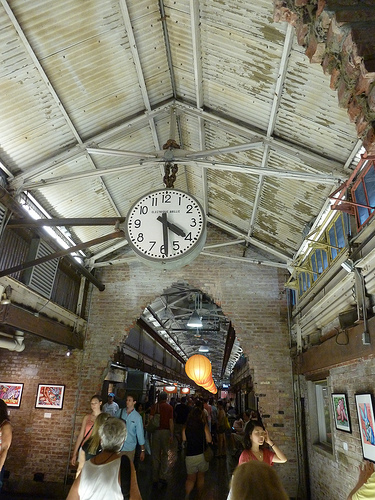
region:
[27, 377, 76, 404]
large picture on wall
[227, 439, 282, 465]
woman wearing red shirt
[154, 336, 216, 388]
large round orange light in ceiling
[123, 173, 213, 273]
large white and gray clock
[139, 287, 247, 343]
silver overhead beams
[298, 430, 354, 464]
gray ledge on window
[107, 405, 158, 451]
man wearing long sleeve blue shirt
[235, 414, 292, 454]
woman holding cell phone to her ear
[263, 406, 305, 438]
black tiles on stone wall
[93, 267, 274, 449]
large arch in doorway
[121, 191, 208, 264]
A clock hanging from above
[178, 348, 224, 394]
A line of orange lights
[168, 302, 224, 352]
a line of industrial lighting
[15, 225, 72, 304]
A vent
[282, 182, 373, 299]
A line of windows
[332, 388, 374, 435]
two pieces of art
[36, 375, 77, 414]
A piece of art on display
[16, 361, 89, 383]
A brick wall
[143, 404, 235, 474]
A large group of people crowded together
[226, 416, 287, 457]
An Asian woman looking at art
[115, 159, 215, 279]
white clock says 4:30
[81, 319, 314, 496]
many people walking through arched door way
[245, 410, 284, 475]
woman with black hair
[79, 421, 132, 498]
woman in white shirt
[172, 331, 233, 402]
many round lights lit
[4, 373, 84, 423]
two photos on wall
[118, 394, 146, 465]
man in blue shirt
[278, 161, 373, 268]
several windows in photo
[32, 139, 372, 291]
several white beams on ceiling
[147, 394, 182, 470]
man carrying bag in photo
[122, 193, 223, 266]
the time is 4:29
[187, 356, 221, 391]
the lights are orange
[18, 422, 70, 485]
the walls are brick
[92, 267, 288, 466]
the arch is in wall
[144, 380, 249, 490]
the people are walking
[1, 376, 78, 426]
art is on wall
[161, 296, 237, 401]
the ceiling is industrial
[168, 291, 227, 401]
lights are hanging from ceiling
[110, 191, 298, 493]
the clock is above people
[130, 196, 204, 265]
the clock face is white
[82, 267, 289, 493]
There is a large hole in the wall.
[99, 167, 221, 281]
A clock above.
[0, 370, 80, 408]
Pictures are hanging on the wall.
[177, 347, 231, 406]
Lights are giving an orange glow.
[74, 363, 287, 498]
Is a crowded area.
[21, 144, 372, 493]
Looks like an old train station.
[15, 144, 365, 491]
An old building being reused for something else.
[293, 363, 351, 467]
A window.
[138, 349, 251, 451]
Looks like a long building.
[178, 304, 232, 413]
Fluorescent lights above the orange ones.